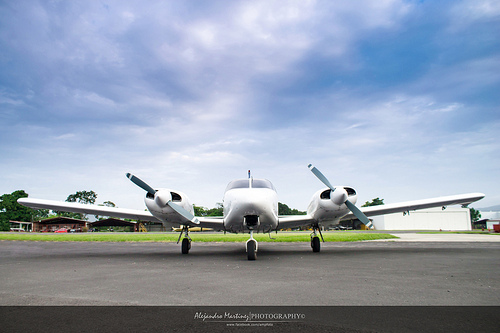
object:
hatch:
[177, 225, 185, 244]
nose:
[224, 188, 280, 209]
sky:
[0, 0, 499, 211]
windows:
[224, 178, 278, 194]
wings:
[17, 192, 486, 226]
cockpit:
[223, 169, 278, 226]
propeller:
[125, 172, 201, 224]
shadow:
[4, 242, 500, 256]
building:
[372, 207, 472, 230]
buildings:
[0, 216, 137, 232]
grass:
[0, 230, 400, 242]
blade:
[125, 172, 157, 194]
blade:
[167, 201, 200, 224]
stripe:
[308, 164, 314, 170]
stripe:
[129, 173, 133, 180]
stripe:
[366, 221, 372, 226]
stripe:
[191, 217, 197, 222]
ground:
[0, 230, 497, 307]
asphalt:
[0, 241, 499, 306]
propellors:
[117, 163, 375, 230]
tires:
[181, 236, 334, 260]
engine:
[124, 172, 200, 225]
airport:
[0, 222, 500, 307]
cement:
[0, 234, 497, 306]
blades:
[307, 163, 375, 230]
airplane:
[17, 163, 485, 259]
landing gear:
[177, 225, 193, 254]